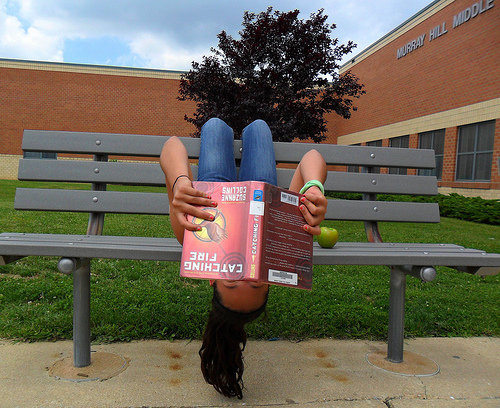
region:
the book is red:
[166, 167, 336, 312]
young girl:
[143, 107, 318, 403]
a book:
[172, 157, 367, 302]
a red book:
[175, 165, 342, 321]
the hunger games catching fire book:
[156, 157, 386, 293]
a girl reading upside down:
[141, 95, 346, 397]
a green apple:
[306, 214, 361, 278]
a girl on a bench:
[18, 114, 483, 382]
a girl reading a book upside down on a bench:
[16, 118, 450, 383]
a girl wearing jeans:
[161, 103, 364, 388]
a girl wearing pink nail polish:
[150, 110, 336, 367]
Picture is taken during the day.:
[17, 13, 491, 347]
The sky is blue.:
[37, 14, 393, 92]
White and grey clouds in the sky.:
[32, 18, 272, 55]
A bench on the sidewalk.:
[31, 127, 473, 272]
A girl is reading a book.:
[157, 92, 336, 378]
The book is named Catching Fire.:
[173, 172, 327, 314]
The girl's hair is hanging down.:
[192, 318, 278, 395]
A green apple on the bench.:
[311, 212, 341, 264]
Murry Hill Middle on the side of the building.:
[384, 33, 498, 77]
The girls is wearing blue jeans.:
[193, 123, 313, 215]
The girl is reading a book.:
[158, 163, 345, 291]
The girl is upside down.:
[142, 115, 353, 405]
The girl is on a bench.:
[0, 108, 498, 403]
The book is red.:
[172, 165, 329, 292]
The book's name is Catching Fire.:
[172, 242, 254, 287]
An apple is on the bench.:
[310, 219, 347, 255]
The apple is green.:
[307, 221, 352, 251]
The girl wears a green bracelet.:
[293, 174, 339, 201]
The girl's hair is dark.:
[195, 290, 265, 405]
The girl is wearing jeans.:
[186, 112, 287, 204]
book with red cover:
[188, 173, 325, 308]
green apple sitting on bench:
[316, 223, 366, 269]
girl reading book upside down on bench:
[136, 104, 338, 406]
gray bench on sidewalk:
[8, 118, 495, 406]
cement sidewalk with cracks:
[18, 323, 497, 405]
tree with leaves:
[185, 8, 367, 144]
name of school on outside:
[386, 1, 499, 64]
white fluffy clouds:
[14, 19, 91, 62]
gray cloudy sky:
[134, 1, 256, 47]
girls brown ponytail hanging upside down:
[198, 283, 282, 406]